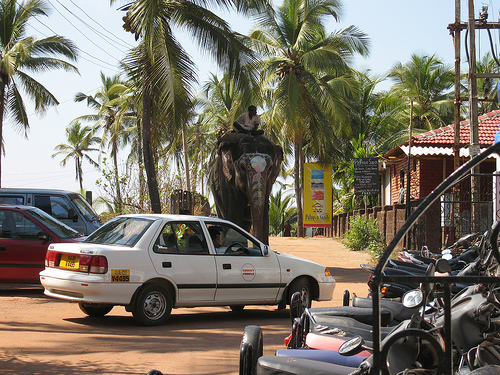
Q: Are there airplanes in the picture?
A: No, there are no airplanes.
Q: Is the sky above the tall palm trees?
A: Yes, the sky is above the palms.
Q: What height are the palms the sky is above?
A: The palm trees are tall.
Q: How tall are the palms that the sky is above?
A: The palms are tall.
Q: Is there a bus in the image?
A: No, there are no buses.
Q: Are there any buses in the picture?
A: No, there are no buses.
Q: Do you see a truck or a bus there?
A: No, there are no buses or trucks.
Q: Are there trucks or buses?
A: No, there are no buses or trucks.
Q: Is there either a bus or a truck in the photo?
A: No, there are no buses or trucks.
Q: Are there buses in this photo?
A: No, there are no buses.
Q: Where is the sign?
A: The sign is on the road.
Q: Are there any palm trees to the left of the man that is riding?
A: Yes, there are palm trees to the left of the man.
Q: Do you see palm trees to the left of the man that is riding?
A: Yes, there are palm trees to the left of the man.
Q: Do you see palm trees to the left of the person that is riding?
A: Yes, there are palm trees to the left of the man.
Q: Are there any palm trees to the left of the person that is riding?
A: Yes, there are palm trees to the left of the man.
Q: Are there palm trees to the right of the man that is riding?
A: No, the palm trees are to the left of the man.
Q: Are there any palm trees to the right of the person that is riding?
A: No, the palm trees are to the left of the man.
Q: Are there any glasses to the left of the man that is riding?
A: No, there are palm trees to the left of the man.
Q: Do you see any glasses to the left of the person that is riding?
A: No, there are palm trees to the left of the man.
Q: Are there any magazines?
A: No, there are no magazines.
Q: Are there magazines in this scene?
A: No, there are no magazines.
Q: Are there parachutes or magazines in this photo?
A: No, there are no magazines or parachutes.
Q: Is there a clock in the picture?
A: No, there are no clocks.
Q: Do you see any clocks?
A: No, there are no clocks.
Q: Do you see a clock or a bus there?
A: No, there are no clocks or buses.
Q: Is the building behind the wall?
A: Yes, the building is behind the wall.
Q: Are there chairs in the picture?
A: No, there are no chairs.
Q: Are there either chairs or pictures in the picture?
A: No, there are no chairs or pictures.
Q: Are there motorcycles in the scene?
A: Yes, there are motorcycles.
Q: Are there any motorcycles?
A: Yes, there are motorcycles.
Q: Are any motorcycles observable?
A: Yes, there are motorcycles.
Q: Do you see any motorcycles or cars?
A: Yes, there are motorcycles.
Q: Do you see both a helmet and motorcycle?
A: No, there are motorcycles but no helmets.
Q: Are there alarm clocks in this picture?
A: No, there are no alarm clocks.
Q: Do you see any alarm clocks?
A: No, there are no alarm clocks.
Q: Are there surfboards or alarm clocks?
A: No, there are no alarm clocks or surfboards.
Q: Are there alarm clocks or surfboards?
A: No, there are no alarm clocks or surfboards.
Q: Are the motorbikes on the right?
A: Yes, the motorbikes are on the right of the image.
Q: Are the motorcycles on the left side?
A: No, the motorcycles are on the right of the image.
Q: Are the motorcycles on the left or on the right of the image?
A: The motorcycles are on the right of the image.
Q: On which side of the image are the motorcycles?
A: The motorcycles are on the right of the image.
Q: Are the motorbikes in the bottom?
A: Yes, the motorbikes are in the bottom of the image.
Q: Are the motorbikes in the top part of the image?
A: No, the motorbikes are in the bottom of the image.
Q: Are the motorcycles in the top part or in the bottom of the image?
A: The motorcycles are in the bottom of the image.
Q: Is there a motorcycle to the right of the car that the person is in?
A: Yes, there are motorcycles to the right of the car.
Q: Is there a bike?
A: Yes, there is a bike.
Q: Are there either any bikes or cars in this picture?
A: Yes, there is a bike.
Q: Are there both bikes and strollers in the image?
A: No, there is a bike but no strollers.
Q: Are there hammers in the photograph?
A: No, there are no hammers.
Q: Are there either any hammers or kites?
A: No, there are no hammers or kites.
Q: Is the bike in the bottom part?
A: Yes, the bike is in the bottom of the image.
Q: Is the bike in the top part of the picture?
A: No, the bike is in the bottom of the image.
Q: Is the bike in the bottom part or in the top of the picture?
A: The bike is in the bottom of the image.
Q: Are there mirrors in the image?
A: Yes, there is a mirror.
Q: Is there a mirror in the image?
A: Yes, there is a mirror.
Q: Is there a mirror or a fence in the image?
A: Yes, there is a mirror.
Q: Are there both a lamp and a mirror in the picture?
A: No, there is a mirror but no lamps.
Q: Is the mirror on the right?
A: Yes, the mirror is on the right of the image.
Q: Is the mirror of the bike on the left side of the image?
A: No, the mirror is on the right of the image.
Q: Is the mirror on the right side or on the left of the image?
A: The mirror is on the right of the image.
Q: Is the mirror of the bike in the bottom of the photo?
A: Yes, the mirror is in the bottom of the image.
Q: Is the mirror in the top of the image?
A: No, the mirror is in the bottom of the image.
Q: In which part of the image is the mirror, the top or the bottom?
A: The mirror is in the bottom of the image.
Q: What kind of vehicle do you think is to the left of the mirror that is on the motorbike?
A: The vehicle is a car.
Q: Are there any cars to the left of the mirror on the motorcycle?
A: Yes, there is a car to the left of the mirror.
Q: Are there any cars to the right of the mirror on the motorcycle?
A: No, the car is to the left of the mirror.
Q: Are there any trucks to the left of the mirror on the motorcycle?
A: No, there is a car to the left of the mirror.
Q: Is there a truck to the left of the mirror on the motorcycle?
A: No, there is a car to the left of the mirror.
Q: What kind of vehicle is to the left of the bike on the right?
A: The vehicle is a car.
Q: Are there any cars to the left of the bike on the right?
A: Yes, there is a car to the left of the bike.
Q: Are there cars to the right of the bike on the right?
A: No, the car is to the left of the bike.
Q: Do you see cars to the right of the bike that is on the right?
A: No, the car is to the left of the bike.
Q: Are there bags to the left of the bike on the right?
A: No, there is a car to the left of the bike.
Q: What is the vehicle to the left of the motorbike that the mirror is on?
A: The vehicle is a car.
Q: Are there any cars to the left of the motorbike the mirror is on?
A: Yes, there is a car to the left of the motorbike.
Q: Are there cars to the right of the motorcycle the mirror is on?
A: No, the car is to the left of the motorbike.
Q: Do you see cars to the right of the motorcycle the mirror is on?
A: No, the car is to the left of the motorbike.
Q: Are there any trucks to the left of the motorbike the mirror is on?
A: No, there is a car to the left of the motorcycle.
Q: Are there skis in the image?
A: No, there are no skis.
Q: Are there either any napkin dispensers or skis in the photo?
A: No, there are no skis or napkin dispensers.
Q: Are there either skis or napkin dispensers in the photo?
A: No, there are no skis or napkin dispensers.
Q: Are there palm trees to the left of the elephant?
A: Yes, there is a palm tree to the left of the elephant.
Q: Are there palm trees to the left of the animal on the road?
A: Yes, there is a palm tree to the left of the elephant.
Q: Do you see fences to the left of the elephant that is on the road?
A: No, there is a palm tree to the left of the elephant.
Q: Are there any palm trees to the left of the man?
A: Yes, there is a palm tree to the left of the man.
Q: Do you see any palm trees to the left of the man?
A: Yes, there is a palm tree to the left of the man.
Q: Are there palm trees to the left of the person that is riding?
A: Yes, there is a palm tree to the left of the man.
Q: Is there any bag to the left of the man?
A: No, there is a palm tree to the left of the man.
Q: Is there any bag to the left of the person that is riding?
A: No, there is a palm tree to the left of the man.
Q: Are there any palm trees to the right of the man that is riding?
A: Yes, there is a palm tree to the right of the man.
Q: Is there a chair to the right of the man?
A: No, there is a palm tree to the right of the man.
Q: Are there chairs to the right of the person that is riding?
A: No, there is a palm tree to the right of the man.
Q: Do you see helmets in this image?
A: No, there are no helmets.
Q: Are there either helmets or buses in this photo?
A: No, there are no helmets or buses.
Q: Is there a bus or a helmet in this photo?
A: No, there are no helmets or buses.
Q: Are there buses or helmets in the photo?
A: No, there are no helmets or buses.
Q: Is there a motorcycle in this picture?
A: Yes, there is a motorcycle.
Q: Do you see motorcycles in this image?
A: Yes, there is a motorcycle.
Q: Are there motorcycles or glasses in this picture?
A: Yes, there is a motorcycle.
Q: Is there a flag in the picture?
A: No, there are no flags.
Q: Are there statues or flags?
A: No, there are no flags or statues.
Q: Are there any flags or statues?
A: No, there are no flags or statues.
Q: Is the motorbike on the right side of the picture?
A: Yes, the motorbike is on the right of the image.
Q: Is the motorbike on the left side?
A: No, the motorbike is on the right of the image.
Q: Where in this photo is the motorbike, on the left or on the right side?
A: The motorbike is on the right of the image.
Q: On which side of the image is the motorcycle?
A: The motorcycle is on the right of the image.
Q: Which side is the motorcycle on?
A: The motorcycle is on the right of the image.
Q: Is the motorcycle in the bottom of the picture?
A: Yes, the motorcycle is in the bottom of the image.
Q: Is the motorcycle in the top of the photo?
A: No, the motorcycle is in the bottom of the image.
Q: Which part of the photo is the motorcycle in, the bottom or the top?
A: The motorcycle is in the bottom of the image.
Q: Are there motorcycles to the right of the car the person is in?
A: Yes, there is a motorcycle to the right of the car.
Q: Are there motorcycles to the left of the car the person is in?
A: No, the motorcycle is to the right of the car.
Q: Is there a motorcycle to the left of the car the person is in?
A: No, the motorcycle is to the right of the car.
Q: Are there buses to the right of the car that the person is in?
A: No, there is a motorcycle to the right of the car.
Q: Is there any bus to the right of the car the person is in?
A: No, there is a motorcycle to the right of the car.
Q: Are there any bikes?
A: Yes, there is a bike.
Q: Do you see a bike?
A: Yes, there is a bike.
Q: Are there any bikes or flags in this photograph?
A: Yes, there is a bike.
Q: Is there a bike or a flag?
A: Yes, there is a bike.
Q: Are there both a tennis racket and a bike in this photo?
A: No, there is a bike but no rackets.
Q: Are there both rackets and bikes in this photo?
A: No, there is a bike but no rackets.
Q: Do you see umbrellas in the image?
A: No, there are no umbrellas.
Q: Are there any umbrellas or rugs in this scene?
A: No, there are no umbrellas or rugs.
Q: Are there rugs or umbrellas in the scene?
A: No, there are no umbrellas or rugs.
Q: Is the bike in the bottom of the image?
A: Yes, the bike is in the bottom of the image.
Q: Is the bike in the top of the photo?
A: No, the bike is in the bottom of the image.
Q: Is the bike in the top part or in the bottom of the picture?
A: The bike is in the bottom of the image.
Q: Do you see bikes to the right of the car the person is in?
A: Yes, there is a bike to the right of the car.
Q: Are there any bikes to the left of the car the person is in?
A: No, the bike is to the right of the car.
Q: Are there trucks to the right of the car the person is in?
A: No, there is a bike to the right of the car.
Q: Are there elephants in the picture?
A: Yes, there is an elephant.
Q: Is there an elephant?
A: Yes, there is an elephant.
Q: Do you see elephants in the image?
A: Yes, there is an elephant.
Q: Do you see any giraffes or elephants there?
A: Yes, there is an elephant.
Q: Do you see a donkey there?
A: No, there are no donkeys.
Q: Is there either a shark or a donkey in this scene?
A: No, there are no donkeys or sharks.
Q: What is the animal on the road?
A: The animal is an elephant.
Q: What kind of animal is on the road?
A: The animal is an elephant.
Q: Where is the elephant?
A: The elephant is on the road.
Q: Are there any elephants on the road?
A: Yes, there is an elephant on the road.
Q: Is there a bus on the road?
A: No, there is an elephant on the road.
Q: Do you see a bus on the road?
A: No, there is an elephant on the road.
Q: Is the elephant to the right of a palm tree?
A: Yes, the elephant is to the right of a palm tree.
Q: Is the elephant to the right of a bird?
A: No, the elephant is to the right of a palm tree.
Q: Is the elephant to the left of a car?
A: No, the elephant is to the right of a car.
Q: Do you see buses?
A: No, there are no buses.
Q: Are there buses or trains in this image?
A: No, there are no buses or trains.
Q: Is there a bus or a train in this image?
A: No, there are no buses or trains.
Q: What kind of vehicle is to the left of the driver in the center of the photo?
A: The vehicle is a car.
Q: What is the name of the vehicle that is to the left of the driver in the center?
A: The vehicle is a car.